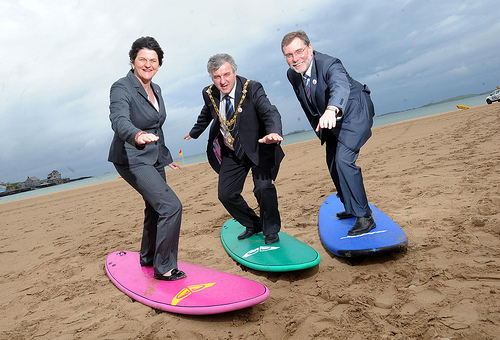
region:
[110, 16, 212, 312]
woman standing on a pink surfboard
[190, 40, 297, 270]
man standing on a green surfboard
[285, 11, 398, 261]
man standing on a blue surfboard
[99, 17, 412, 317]
people in business suits standing on surfboards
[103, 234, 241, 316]
pink and yellow surfboard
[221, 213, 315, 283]
green and white surfboard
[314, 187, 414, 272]
blue and white surfboard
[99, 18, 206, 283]
woman wearing a grey business suit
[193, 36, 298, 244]
man wearing a black business suit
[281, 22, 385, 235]
man wearing a grey business suit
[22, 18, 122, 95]
white clouds in blue sky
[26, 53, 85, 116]
white clouds in blue sky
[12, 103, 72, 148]
white clouds in blue sky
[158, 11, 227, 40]
white clouds in blue sky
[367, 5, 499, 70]
white clouds in blue sky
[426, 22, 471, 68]
white clouds in blue sky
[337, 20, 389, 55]
white clouds in blue sky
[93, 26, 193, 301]
person standing on surf board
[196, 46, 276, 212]
person standing on surf board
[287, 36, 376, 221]
person standing on surf board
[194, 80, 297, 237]
the man is wearing a business suit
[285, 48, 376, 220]
the man is wearing a business suit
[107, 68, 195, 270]
the woman is wearing a business suit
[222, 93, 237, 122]
the man is wearing a tie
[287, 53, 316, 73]
the man has a beard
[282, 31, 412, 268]
the man is on a surfboard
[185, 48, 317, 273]
the man is on a surfboard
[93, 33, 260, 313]
the woman is on a surfboard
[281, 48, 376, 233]
the suit is grey in color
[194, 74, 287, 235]
the suit is black in color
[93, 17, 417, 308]
Three business people on surfboards on the sand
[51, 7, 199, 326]
A woman on a pink surfboard on the sand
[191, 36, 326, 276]
Man on green surfboard on the sand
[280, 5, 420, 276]
Man on a blue surfboard on sand at the beach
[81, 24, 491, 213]
3 people in business suits on the beach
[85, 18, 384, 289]
3 business people posing on surfboards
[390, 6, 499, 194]
Lifeguard patrolling beach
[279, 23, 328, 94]
Man with brown hair and gray beard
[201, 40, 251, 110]
Man with gray hair in a tie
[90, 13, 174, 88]
Woman with very short haircut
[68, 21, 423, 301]
Business people on surfboards.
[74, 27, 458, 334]
People in suits on surfboards.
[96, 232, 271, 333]
Pink surfboard on the sand.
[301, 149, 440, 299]
Blue surfboard on the sand.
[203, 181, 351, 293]
Green surfboard on the sand.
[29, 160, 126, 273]
Sand on the beach.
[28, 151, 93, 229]
Water against the sand.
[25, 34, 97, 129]
White clouds in the sky.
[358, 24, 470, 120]
Blue sky with white clouds.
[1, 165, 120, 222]
Island in the water.